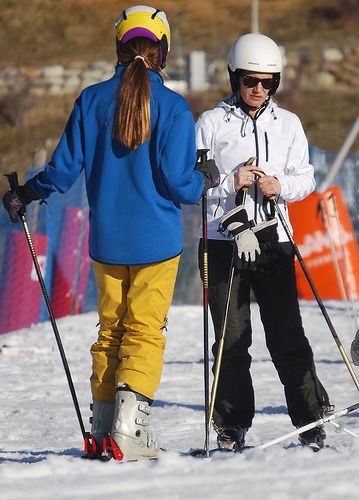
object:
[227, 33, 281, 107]
man head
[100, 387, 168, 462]
boots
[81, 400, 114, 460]
ski boot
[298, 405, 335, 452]
ski boot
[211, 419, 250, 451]
ski boot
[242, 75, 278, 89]
glasses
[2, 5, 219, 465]
man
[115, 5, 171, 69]
helmet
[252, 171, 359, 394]
pole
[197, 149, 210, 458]
ski pole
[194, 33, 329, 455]
man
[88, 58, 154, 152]
ponytail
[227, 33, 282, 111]
helmet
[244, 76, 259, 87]
eyes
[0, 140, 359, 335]
barrier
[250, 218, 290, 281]
gloves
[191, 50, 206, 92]
floor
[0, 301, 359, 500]
snow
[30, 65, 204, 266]
sweater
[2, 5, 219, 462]
girl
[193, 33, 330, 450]
girl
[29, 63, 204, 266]
jacket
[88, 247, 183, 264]
trim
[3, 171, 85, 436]
pole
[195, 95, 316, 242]
sweater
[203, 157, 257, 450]
poles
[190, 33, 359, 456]
skis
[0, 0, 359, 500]
course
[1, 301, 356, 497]
ski slope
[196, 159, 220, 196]
woman's hand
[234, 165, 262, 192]
woman's hand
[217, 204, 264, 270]
glove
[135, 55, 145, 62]
ponytail holder